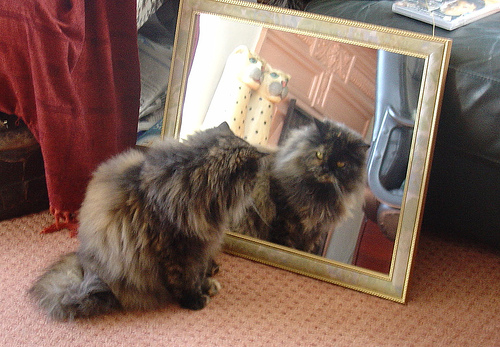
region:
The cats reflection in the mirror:
[278, 105, 375, 219]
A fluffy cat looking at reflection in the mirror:
[26, 116, 275, 328]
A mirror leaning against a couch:
[168, 28, 459, 308]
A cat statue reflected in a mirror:
[204, 38, 297, 148]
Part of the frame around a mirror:
[403, 28, 454, 62]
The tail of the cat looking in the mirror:
[23, 248, 120, 325]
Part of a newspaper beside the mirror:
[138, 32, 162, 110]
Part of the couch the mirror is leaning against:
[456, 35, 498, 248]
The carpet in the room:
[238, 270, 295, 339]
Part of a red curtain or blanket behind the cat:
[34, 33, 138, 137]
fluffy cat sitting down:
[16, 111, 261, 325]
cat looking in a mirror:
[28, 4, 450, 328]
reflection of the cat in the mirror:
[244, 91, 376, 259]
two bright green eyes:
[310, 146, 350, 173]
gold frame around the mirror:
[142, 2, 432, 309]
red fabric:
[0, 3, 160, 238]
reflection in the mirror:
[180, 15, 408, 285]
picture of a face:
[436, 0, 486, 24]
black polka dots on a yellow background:
[247, 90, 274, 143]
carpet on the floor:
[1, 193, 498, 345]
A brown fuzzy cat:
[40, 121, 246, 313]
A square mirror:
[162, 0, 454, 310]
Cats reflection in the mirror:
[263, 110, 374, 240]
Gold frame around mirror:
[267, 26, 458, 301]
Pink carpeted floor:
[221, 283, 338, 343]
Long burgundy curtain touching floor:
[7, 5, 137, 150]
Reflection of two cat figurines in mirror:
[210, 37, 295, 137]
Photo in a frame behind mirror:
[391, 0, 493, 25]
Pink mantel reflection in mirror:
[266, 50, 381, 97]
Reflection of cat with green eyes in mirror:
[301, 140, 358, 182]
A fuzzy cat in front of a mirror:
[18, 120, 268, 325]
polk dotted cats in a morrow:
[196, 38, 305, 115]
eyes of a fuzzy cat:
[310, 145, 366, 171]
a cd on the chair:
[387, 0, 493, 25]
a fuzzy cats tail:
[31, 239, 97, 331]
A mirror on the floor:
[142, 0, 458, 310]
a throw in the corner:
[3, 0, 133, 192]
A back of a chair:
[353, 73, 435, 225]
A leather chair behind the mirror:
[429, 0, 499, 225]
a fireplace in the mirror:
[252, 43, 384, 138]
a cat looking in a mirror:
[68, 85, 431, 340]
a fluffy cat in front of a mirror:
[21, 100, 332, 338]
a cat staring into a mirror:
[59, 110, 373, 339]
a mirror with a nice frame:
[168, 9, 423, 284]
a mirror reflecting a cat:
[141, 5, 458, 282]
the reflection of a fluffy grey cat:
[287, 117, 380, 215]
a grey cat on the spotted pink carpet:
[74, 119, 312, 345]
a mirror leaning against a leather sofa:
[162, 5, 485, 230]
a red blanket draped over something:
[13, 5, 160, 227]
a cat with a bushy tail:
[5, 124, 260, 311]